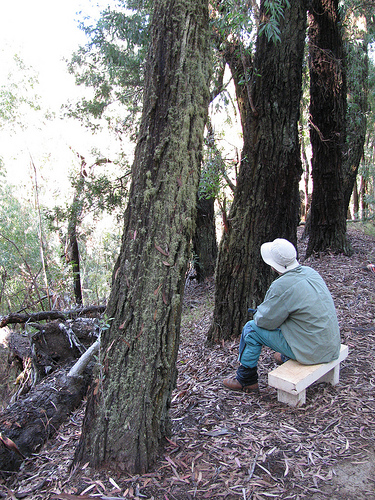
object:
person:
[223, 238, 342, 393]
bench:
[267, 342, 348, 407]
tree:
[69, 0, 213, 480]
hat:
[260, 238, 300, 274]